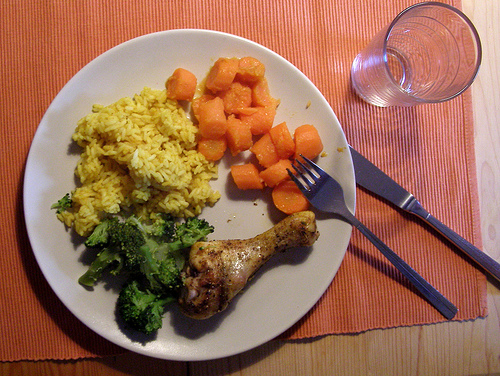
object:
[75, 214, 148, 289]
broccoli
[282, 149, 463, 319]
fork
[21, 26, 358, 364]
plate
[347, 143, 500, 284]
knife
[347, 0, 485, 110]
glass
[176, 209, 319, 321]
chicken leg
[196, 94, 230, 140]
carrots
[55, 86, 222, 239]
rice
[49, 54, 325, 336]
meal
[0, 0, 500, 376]
placemat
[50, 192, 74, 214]
broccoli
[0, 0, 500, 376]
table